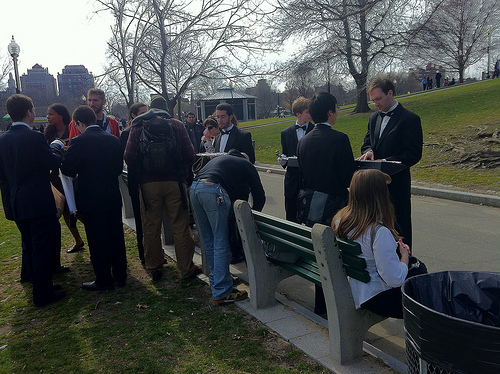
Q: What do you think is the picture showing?
A: It is showing a park.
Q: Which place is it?
A: It is a park.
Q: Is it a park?
A: Yes, it is a park.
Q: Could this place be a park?
A: Yes, it is a park.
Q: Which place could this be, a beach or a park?
A: It is a park.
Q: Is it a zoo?
A: No, it is a park.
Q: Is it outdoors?
A: Yes, it is outdoors.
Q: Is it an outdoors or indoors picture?
A: It is outdoors.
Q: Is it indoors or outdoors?
A: It is outdoors.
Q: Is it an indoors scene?
A: No, it is outdoors.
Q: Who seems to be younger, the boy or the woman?
A: The boy is younger than the woman.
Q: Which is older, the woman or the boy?
A: The woman is older than the boy.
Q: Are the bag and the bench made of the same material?
A: No, the bag is made of plastic and the bench is made of cement.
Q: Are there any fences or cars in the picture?
A: No, there are no cars or fences.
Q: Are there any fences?
A: No, there are no fences.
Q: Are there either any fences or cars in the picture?
A: No, there are no fences or cars.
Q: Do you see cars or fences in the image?
A: No, there are no fences or cars.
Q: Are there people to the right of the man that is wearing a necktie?
A: Yes, there are people to the right of the man.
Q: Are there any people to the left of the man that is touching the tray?
A: No, the people are to the right of the man.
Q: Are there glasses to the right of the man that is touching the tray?
A: No, there are people to the right of the man.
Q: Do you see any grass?
A: Yes, there is grass.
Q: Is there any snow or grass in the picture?
A: Yes, there is grass.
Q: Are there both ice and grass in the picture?
A: No, there is grass but no ice.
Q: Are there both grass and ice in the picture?
A: No, there is grass but no ice.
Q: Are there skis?
A: No, there are no skis.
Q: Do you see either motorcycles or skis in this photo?
A: No, there are no skis or motorcycles.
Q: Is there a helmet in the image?
A: No, there are no helmets.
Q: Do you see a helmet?
A: No, there are no helmets.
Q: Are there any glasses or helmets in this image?
A: No, there are no helmets or glasses.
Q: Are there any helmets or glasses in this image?
A: No, there are no helmets or glasses.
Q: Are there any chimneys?
A: No, there are no chimneys.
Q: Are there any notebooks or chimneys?
A: No, there are no chimneys or notebooks.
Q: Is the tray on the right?
A: Yes, the tray is on the right of the image.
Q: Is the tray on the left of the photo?
A: No, the tray is on the right of the image.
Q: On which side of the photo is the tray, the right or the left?
A: The tray is on the right of the image.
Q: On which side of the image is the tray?
A: The tray is on the right of the image.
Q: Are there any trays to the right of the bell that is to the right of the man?
A: Yes, there is a tray to the right of the bell.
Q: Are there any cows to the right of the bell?
A: No, there is a tray to the right of the bell.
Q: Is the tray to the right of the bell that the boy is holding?
A: Yes, the tray is to the right of the bell.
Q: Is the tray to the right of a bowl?
A: No, the tray is to the right of the bell.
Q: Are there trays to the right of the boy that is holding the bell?
A: Yes, there is a tray to the right of the boy.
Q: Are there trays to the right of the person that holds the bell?
A: Yes, there is a tray to the right of the boy.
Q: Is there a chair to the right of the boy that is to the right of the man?
A: No, there is a tray to the right of the boy.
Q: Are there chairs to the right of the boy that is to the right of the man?
A: No, there is a tray to the right of the boy.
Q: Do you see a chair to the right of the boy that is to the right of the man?
A: No, there is a tray to the right of the boy.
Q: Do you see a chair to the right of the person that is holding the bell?
A: No, there is a tray to the right of the boy.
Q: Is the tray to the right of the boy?
A: Yes, the tray is to the right of the boy.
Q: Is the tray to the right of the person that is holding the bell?
A: Yes, the tray is to the right of the boy.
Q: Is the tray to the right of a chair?
A: No, the tray is to the right of the boy.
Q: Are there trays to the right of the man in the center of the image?
A: Yes, there is a tray to the right of the man.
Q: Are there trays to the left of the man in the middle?
A: No, the tray is to the right of the man.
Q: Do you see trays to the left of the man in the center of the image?
A: No, the tray is to the right of the man.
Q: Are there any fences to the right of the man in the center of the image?
A: No, there is a tray to the right of the man.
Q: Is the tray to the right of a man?
A: Yes, the tray is to the right of a man.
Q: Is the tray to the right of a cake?
A: No, the tray is to the right of a man.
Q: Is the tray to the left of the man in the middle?
A: No, the tray is to the right of the man.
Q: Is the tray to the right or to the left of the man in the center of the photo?
A: The tray is to the right of the man.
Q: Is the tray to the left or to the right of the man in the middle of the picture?
A: The tray is to the right of the man.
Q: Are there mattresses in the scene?
A: No, there are no mattresses.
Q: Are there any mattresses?
A: No, there are no mattresses.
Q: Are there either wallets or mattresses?
A: No, there are no mattresses or wallets.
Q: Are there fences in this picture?
A: No, there are no fences.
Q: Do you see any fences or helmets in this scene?
A: No, there are no fences or helmets.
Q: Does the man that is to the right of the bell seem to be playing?
A: Yes, the man is playing.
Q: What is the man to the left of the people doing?
A: The man is playing.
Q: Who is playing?
A: The man is playing.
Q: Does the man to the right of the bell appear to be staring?
A: No, the man is playing.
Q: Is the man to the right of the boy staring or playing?
A: The man is playing.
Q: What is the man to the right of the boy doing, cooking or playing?
A: The man is playing.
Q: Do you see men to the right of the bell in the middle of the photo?
A: Yes, there is a man to the right of the bell.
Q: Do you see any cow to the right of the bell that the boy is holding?
A: No, there is a man to the right of the bell.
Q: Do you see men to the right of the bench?
A: Yes, there is a man to the right of the bench.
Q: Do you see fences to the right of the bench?
A: No, there is a man to the right of the bench.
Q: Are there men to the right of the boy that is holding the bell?
A: Yes, there is a man to the right of the boy.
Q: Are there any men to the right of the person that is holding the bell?
A: Yes, there is a man to the right of the boy.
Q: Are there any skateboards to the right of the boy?
A: No, there is a man to the right of the boy.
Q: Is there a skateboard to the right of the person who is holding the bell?
A: No, there is a man to the right of the boy.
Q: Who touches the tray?
A: The man touches the tray.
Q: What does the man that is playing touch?
A: The man touches the tray.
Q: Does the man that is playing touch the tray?
A: Yes, the man touches the tray.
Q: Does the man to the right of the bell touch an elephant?
A: No, the man touches the tray.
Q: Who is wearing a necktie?
A: The man is wearing a necktie.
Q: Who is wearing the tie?
A: The man is wearing a necktie.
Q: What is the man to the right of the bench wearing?
A: The man is wearing a tie.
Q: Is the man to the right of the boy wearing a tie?
A: Yes, the man is wearing a tie.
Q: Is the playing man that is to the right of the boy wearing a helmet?
A: No, the man is wearing a tie.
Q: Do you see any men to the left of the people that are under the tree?
A: Yes, there is a man to the left of the people.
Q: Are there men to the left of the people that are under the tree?
A: Yes, there is a man to the left of the people.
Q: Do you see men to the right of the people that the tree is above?
A: No, the man is to the left of the people.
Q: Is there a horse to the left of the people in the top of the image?
A: No, there is a man to the left of the people.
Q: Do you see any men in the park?
A: Yes, there is a man in the park.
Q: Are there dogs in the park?
A: No, there is a man in the park.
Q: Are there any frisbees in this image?
A: No, there are no frisbees.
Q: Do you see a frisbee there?
A: No, there are no frisbees.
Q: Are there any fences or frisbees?
A: No, there are no frisbees or fences.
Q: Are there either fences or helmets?
A: No, there are no helmets or fences.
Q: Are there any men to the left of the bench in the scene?
A: Yes, there is a man to the left of the bench.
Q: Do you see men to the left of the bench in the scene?
A: Yes, there is a man to the left of the bench.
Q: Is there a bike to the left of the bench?
A: No, there is a man to the left of the bench.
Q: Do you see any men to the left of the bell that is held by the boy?
A: Yes, there is a man to the left of the bell.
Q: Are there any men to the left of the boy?
A: Yes, there is a man to the left of the boy.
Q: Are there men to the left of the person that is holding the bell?
A: Yes, there is a man to the left of the boy.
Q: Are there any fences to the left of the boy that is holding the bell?
A: No, there is a man to the left of the boy.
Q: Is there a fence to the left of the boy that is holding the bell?
A: No, there is a man to the left of the boy.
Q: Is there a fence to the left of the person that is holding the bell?
A: No, there is a man to the left of the boy.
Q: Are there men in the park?
A: Yes, there is a man in the park.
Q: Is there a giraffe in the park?
A: No, there is a man in the park.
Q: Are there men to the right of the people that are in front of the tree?
A: Yes, there is a man to the right of the people.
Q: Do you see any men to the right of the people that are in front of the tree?
A: Yes, there is a man to the right of the people.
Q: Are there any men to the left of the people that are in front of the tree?
A: No, the man is to the right of the people.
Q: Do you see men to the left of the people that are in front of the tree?
A: No, the man is to the right of the people.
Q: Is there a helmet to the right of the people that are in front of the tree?
A: No, there is a man to the right of the people.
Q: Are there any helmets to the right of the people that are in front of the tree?
A: No, there is a man to the right of the people.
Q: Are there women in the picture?
A: Yes, there is a woman.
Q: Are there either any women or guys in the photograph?
A: Yes, there is a woman.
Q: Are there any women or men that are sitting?
A: Yes, the woman is sitting.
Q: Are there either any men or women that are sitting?
A: Yes, the woman is sitting.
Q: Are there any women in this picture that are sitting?
A: Yes, there is a woman that is sitting.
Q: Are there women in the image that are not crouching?
A: Yes, there is a woman that is sitting.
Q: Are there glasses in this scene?
A: No, there are no glasses.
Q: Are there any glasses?
A: No, there are no glasses.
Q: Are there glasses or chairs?
A: No, there are no glasses or chairs.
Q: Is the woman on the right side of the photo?
A: Yes, the woman is on the right of the image.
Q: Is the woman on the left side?
A: No, the woman is on the right of the image.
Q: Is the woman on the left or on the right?
A: The woman is on the right of the image.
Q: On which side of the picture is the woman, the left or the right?
A: The woman is on the right of the image.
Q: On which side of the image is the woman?
A: The woman is on the right of the image.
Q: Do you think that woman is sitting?
A: Yes, the woman is sitting.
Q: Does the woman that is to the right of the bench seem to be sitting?
A: Yes, the woman is sitting.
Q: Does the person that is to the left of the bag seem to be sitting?
A: Yes, the woman is sitting.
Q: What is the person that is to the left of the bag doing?
A: The woman is sitting.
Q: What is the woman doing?
A: The woman is sitting.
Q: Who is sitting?
A: The woman is sitting.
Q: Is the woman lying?
A: No, the woman is sitting.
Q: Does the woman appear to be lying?
A: No, the woman is sitting.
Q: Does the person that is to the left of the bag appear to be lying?
A: No, the woman is sitting.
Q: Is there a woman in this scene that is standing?
A: No, there is a woman but she is sitting.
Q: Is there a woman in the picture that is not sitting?
A: No, there is a woman but she is sitting.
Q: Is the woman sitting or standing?
A: The woman is sitting.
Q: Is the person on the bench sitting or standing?
A: The woman is sitting.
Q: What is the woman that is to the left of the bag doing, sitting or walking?
A: The woman is sitting.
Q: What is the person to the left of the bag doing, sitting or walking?
A: The woman is sitting.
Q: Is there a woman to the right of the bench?
A: Yes, there is a woman to the right of the bench.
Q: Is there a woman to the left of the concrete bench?
A: No, the woman is to the right of the bench.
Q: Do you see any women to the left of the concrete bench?
A: No, the woman is to the right of the bench.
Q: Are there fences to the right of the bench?
A: No, there is a woman to the right of the bench.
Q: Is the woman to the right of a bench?
A: Yes, the woman is to the right of a bench.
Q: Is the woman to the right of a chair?
A: No, the woman is to the right of a bench.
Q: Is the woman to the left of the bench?
A: No, the woman is to the right of the bench.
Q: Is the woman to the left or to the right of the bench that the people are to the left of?
A: The woman is to the right of the bench.